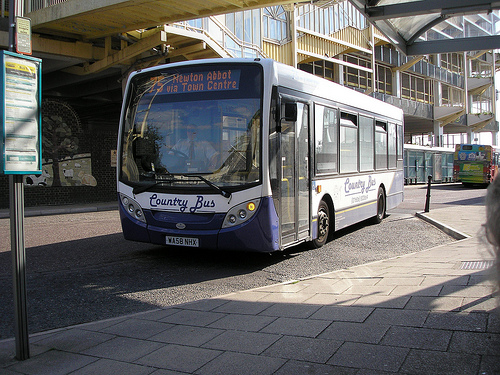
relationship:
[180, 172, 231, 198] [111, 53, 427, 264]
windshield wiper on bus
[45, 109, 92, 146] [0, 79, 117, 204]
brick in wall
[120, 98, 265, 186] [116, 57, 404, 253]
windshield on bus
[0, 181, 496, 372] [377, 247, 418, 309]
shadow on ground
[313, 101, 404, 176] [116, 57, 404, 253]
bus windows on bus